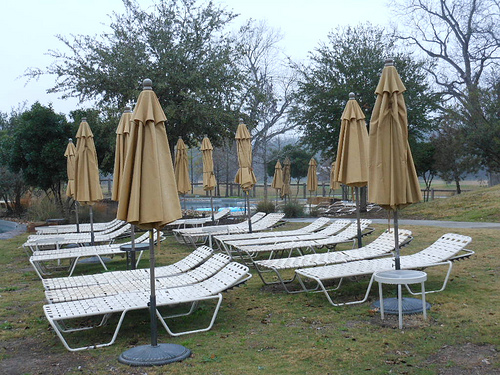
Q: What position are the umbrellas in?
A: Closes.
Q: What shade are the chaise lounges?
A: White.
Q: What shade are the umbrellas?
A: Brown.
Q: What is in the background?
A: Trees.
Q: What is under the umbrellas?
A: Chairs.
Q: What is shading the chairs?
A: The umbrellas.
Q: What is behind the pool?
A: Trees.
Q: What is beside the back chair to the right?
A: A table.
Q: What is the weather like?
A: Cloudy.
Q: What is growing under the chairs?
A: Grass.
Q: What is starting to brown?
A: The grass.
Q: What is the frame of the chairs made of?
A: Metal.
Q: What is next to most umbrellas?
A: A lounge chair.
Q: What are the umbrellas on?
A: Stands.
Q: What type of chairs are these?
A: Lounge chairs.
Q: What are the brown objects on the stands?
A: Umbrellas.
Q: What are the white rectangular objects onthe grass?
A: Lounge chairs.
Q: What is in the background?
A: Trees.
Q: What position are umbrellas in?
A: Closed.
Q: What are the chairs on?
A: The grass.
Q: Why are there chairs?
A: For people recline and sit.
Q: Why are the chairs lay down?
A: They are recliners.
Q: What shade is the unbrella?
A: Brown.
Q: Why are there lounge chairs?
A: For people to sit near the pool.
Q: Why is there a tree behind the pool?
A: For landscaping.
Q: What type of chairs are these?
A: Lawn chairs.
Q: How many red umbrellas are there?
A: None.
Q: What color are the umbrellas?
A: Brown.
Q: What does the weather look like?
A: Rainy.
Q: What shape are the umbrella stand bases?
A: Round.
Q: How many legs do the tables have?
A: 3.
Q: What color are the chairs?
A: White.